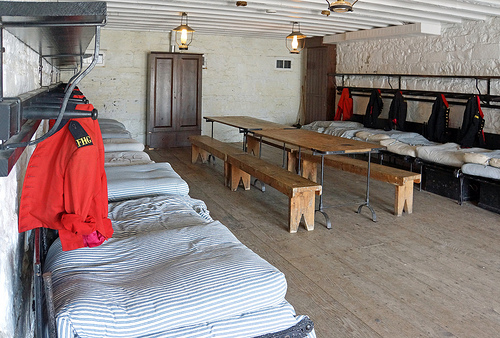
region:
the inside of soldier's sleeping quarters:
[6, 11, 490, 304]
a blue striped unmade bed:
[34, 226, 294, 335]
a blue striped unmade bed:
[105, 160, 192, 197]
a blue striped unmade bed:
[464, 145, 498, 177]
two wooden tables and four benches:
[187, 105, 422, 218]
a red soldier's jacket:
[16, 123, 109, 245]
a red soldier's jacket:
[334, 86, 354, 119]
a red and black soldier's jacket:
[358, 86, 385, 130]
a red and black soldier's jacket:
[389, 85, 410, 134]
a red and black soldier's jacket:
[424, 85, 453, 147]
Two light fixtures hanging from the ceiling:
[166, 2, 308, 59]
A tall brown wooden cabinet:
[136, 45, 207, 152]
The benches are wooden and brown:
[180, 126, 325, 237]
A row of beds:
[30, 112, 321, 332]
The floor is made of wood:
[140, 135, 495, 332]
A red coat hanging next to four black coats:
[321, 80, 491, 147]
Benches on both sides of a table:
[180, 110, 422, 240]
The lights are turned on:
[165, 20, 305, 55]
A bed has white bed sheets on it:
[36, 215, 301, 335]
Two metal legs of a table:
[307, 151, 380, 232]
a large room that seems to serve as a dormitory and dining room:
[1, 2, 495, 336]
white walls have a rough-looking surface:
[0, 16, 497, 336]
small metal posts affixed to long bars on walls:
[0, 0, 498, 177]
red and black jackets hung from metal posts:
[0, 83, 499, 251]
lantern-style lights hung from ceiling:
[171, 0, 358, 54]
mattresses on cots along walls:
[29, 111, 498, 336]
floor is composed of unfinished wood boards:
[146, 142, 499, 337]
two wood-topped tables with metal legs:
[204, 115, 382, 230]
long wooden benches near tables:
[188, 115, 421, 232]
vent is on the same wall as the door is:
[61, 29, 303, 151]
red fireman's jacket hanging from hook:
[17, 86, 112, 251]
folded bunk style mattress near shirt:
[35, 195, 305, 330]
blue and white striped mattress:
[54, 191, 298, 333]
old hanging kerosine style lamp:
[171, 8, 199, 50]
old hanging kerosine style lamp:
[285, 23, 307, 54]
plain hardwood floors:
[147, 143, 499, 333]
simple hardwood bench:
[224, 152, 321, 234]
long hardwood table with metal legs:
[248, 120, 388, 229]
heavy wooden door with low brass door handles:
[145, 53, 204, 145]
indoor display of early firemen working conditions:
[4, 10, 498, 329]